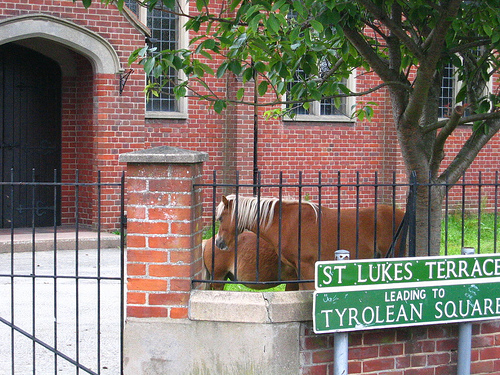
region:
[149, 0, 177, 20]
window of a building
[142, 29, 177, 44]
window of a building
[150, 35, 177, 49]
window of a building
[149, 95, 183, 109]
window of a building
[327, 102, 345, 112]
window of a building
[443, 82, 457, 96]
window of a building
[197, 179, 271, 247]
head of a horse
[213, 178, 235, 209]
ear of a horse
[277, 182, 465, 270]
body of a horse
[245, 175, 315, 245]
neck of a horse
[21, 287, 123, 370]
the gates are skinney and black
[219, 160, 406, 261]
the two horses are standing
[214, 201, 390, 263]
the two horses are brown and blonde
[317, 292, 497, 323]
the signs are green in color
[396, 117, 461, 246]
the tree bark is brown in color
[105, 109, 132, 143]
the building is brick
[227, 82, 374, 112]
the tree leaf is green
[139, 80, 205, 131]
there were four windows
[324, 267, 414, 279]
on the sign it says st luke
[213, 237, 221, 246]
the horse mouth is black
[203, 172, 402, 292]
horses on the lawn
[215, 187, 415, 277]
horse standing up on lawn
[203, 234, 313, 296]
horse leaning over on lawn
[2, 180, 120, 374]
fence to allow vehicles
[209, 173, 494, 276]
fence around the building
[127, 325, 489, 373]
brick and stone wall surrounding building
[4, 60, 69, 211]
doors to the building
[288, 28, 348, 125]
window to the building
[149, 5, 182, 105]
window to the building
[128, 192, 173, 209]
red brick on pole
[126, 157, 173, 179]
red brick on pole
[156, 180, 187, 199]
red brick on pole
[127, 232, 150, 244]
red brick on pole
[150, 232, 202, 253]
red brick on pole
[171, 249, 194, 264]
red brick on pole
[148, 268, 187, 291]
red brick on pole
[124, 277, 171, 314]
red brick on pole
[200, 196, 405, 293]
two horses in a yard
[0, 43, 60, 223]
a large black door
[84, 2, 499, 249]
a tree in the yard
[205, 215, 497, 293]
a green grass yard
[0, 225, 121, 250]
the step up to the door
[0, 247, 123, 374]
sidewalk leading to door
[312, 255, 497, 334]
two green signs with white lettering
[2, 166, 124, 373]
black iron gate on fence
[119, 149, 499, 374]
brick, concrete and iron fence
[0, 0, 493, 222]
a large red brick building